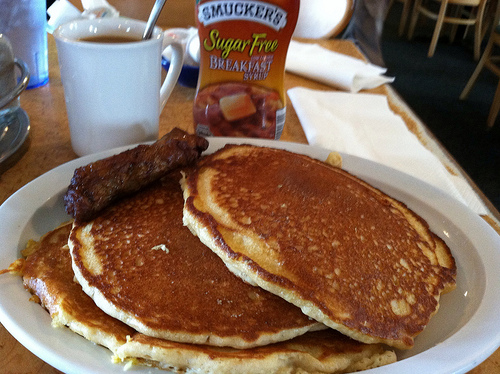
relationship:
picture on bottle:
[192, 82, 287, 139] [190, 2, 302, 140]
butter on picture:
[218, 92, 259, 124] [192, 82, 287, 139]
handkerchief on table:
[284, 85, 489, 219] [0, 4, 497, 373]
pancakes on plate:
[2, 143, 459, 373] [3, 136, 498, 373]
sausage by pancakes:
[59, 126, 211, 225] [2, 143, 459, 373]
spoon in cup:
[139, 2, 167, 42] [51, 16, 186, 157]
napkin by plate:
[284, 85, 489, 219] [3, 136, 498, 373]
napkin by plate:
[284, 40, 398, 94] [3, 136, 498, 373]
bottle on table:
[190, 2, 302, 140] [0, 4, 497, 373]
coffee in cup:
[72, 31, 156, 44] [51, 16, 186, 157]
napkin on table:
[284, 40, 398, 94] [0, 4, 497, 373]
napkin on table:
[284, 85, 489, 219] [0, 4, 497, 373]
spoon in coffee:
[139, 2, 167, 42] [72, 31, 156, 44]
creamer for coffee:
[158, 26, 198, 65] [72, 31, 156, 44]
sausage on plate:
[59, 126, 211, 225] [3, 136, 498, 373]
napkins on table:
[283, 41, 493, 218] [0, 4, 497, 373]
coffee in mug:
[72, 31, 156, 44] [51, 16, 186, 157]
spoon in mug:
[139, 2, 167, 42] [51, 16, 186, 157]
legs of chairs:
[397, 1, 500, 131] [397, 0, 500, 126]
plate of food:
[3, 136, 498, 373] [17, 127, 460, 372]